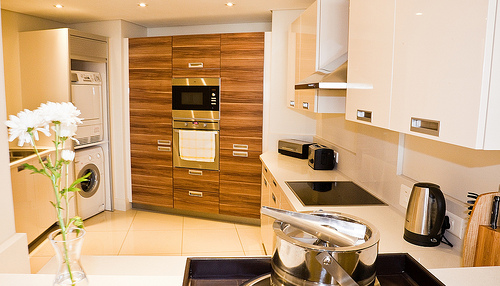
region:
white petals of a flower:
[47, 105, 69, 114]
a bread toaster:
[311, 144, 332, 159]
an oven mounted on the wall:
[177, 82, 217, 109]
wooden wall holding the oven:
[141, 84, 153, 130]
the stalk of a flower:
[49, 181, 64, 205]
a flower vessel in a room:
[56, 252, 83, 284]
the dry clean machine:
[86, 152, 101, 174]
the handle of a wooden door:
[233, 150, 249, 157]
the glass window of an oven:
[183, 93, 202, 103]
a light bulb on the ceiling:
[53, 3, 65, 11]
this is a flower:
[26, 100, 113, 265]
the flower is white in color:
[43, 101, 68, 123]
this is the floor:
[118, 209, 198, 246]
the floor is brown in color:
[129, 209, 160, 240]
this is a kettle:
[392, 183, 435, 230]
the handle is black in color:
[428, 179, 452, 243]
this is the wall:
[261, 17, 293, 107]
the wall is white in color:
[268, 36, 280, 74]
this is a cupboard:
[368, 32, 469, 148]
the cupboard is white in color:
[373, 30, 475, 107]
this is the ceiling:
[180, 6, 202, 18]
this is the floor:
[111, 210, 168, 247]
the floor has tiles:
[121, 221, 166, 249]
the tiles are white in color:
[118, 210, 158, 257]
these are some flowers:
[11, 103, 98, 283]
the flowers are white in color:
[33, 105, 64, 118]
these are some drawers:
[132, 38, 249, 218]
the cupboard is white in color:
[421, 103, 452, 113]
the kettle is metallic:
[408, 203, 422, 218]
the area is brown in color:
[235, 175, 260, 202]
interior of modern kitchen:
[0, 2, 497, 284]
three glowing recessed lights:
[52, 1, 237, 10]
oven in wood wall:
[129, 35, 261, 215]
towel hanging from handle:
[177, 128, 217, 161]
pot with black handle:
[404, 180, 447, 245]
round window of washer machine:
[76, 163, 101, 198]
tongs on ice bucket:
[264, 201, 380, 284]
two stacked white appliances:
[74, 70, 107, 221]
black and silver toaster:
[309, 142, 335, 169]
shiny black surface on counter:
[287, 179, 384, 206]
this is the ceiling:
[158, 4, 184, 17]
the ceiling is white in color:
[180, 1, 200, 15]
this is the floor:
[110, 225, 167, 277]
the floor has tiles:
[117, 220, 152, 261]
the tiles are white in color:
[108, 221, 172, 270]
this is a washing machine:
[73, 150, 100, 204]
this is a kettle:
[401, 174, 451, 251]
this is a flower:
[1, 101, 86, 173]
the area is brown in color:
[176, 42, 205, 52]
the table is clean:
[381, 203, 398, 240]